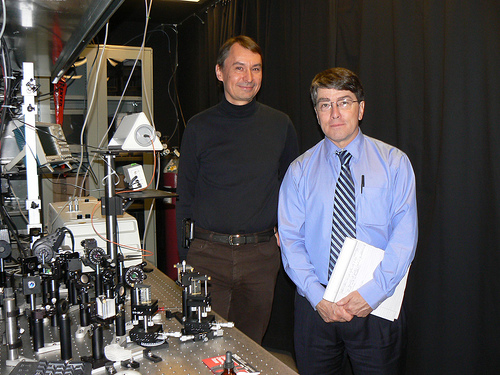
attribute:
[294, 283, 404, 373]
pants — blue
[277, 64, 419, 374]
man — standing, old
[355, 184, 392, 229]
pocket — breast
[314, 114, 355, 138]
mouth — old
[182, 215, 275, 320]
pants — brown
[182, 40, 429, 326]
scientists — posing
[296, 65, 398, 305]
man — old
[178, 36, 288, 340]
man — long sleeved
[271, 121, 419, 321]
shirt — long sleeved, blue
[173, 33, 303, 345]
man — standing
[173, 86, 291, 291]
shirt — dark